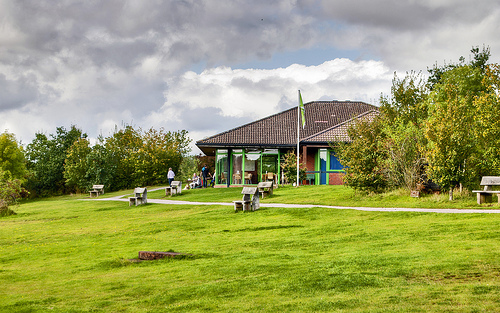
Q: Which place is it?
A: It is a field.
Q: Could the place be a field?
A: Yes, it is a field.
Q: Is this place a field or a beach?
A: It is a field.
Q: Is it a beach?
A: No, it is a field.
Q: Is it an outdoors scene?
A: Yes, it is outdoors.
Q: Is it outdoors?
A: Yes, it is outdoors.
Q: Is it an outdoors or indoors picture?
A: It is outdoors.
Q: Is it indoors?
A: No, it is outdoors.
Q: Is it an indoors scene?
A: No, it is outdoors.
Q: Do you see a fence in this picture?
A: No, there are no fences.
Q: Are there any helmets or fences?
A: No, there are no fences or helmets.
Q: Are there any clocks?
A: No, there are no clocks.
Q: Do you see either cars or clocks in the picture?
A: No, there are no clocks or cars.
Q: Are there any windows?
A: Yes, there is a window.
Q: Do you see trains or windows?
A: Yes, there is a window.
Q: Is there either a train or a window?
A: Yes, there is a window.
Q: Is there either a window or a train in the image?
A: Yes, there is a window.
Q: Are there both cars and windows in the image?
A: No, there is a window but no cars.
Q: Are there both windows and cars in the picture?
A: No, there is a window but no cars.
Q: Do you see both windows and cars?
A: No, there is a window but no cars.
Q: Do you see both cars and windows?
A: No, there is a window but no cars.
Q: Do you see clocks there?
A: No, there are no clocks.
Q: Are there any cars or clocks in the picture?
A: No, there are no clocks or cars.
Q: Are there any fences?
A: No, there are no fences.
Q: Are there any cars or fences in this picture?
A: No, there are no fences or cars.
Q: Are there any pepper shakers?
A: No, there are no pepper shakers.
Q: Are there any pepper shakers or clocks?
A: No, there are no pepper shakers or clocks.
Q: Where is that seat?
A: The seat is on the grass.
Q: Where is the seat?
A: The seat is on the grass.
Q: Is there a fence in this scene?
A: No, there are no fences.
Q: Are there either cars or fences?
A: No, there are no fences or cars.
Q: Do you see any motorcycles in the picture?
A: No, there are no motorcycles.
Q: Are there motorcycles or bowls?
A: No, there are no motorcycles or bowls.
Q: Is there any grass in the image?
A: Yes, there is grass.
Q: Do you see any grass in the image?
A: Yes, there is grass.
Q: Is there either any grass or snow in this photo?
A: Yes, there is grass.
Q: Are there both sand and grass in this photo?
A: No, there is grass but no sand.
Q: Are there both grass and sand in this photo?
A: No, there is grass but no sand.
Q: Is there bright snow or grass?
A: Yes, there is bright grass.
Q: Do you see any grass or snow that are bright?
A: Yes, the grass is bright.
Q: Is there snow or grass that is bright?
A: Yes, the grass is bright.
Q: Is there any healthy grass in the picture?
A: Yes, there is healthy grass.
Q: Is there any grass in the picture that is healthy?
A: Yes, there is grass that is healthy.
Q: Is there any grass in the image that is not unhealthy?
A: Yes, there is healthy grass.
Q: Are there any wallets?
A: No, there are no wallets.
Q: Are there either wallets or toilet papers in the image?
A: No, there are no wallets or toilet papers.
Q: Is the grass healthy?
A: Yes, the grass is healthy.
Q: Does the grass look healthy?
A: Yes, the grass is healthy.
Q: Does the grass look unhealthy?
A: No, the grass is healthy.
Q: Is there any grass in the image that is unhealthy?
A: No, there is grass but it is healthy.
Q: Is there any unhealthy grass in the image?
A: No, there is grass but it is healthy.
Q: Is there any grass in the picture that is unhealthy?
A: No, there is grass but it is healthy.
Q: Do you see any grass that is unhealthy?
A: No, there is grass but it is healthy.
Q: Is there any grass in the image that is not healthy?
A: No, there is grass but it is healthy.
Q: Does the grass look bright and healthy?
A: Yes, the grass is bright and healthy.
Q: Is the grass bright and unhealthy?
A: No, the grass is bright but healthy.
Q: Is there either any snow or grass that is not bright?
A: No, there is grass but it is bright.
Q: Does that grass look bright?
A: Yes, the grass is bright.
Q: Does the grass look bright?
A: Yes, the grass is bright.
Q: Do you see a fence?
A: No, there are no fences.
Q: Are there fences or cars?
A: No, there are no fences or cars.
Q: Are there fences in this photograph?
A: No, there are no fences.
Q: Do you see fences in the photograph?
A: No, there are no fences.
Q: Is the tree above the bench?
A: Yes, the tree is above the bench.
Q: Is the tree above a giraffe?
A: No, the tree is above the bench.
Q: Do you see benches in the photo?
A: Yes, there is a bench.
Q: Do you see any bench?
A: Yes, there is a bench.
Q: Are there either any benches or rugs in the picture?
A: Yes, there is a bench.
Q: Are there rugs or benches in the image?
A: Yes, there is a bench.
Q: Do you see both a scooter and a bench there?
A: No, there is a bench but no scooters.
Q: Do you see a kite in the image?
A: No, there are no kites.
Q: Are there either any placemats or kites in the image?
A: No, there are no kites or placemats.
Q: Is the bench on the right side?
A: Yes, the bench is on the right of the image.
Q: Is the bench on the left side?
A: No, the bench is on the right of the image.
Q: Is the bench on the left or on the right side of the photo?
A: The bench is on the right of the image.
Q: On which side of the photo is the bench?
A: The bench is on the right of the image.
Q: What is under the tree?
A: The bench is under the tree.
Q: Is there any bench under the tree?
A: Yes, there is a bench under the tree.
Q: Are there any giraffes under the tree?
A: No, there is a bench under the tree.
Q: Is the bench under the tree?
A: Yes, the bench is under the tree.